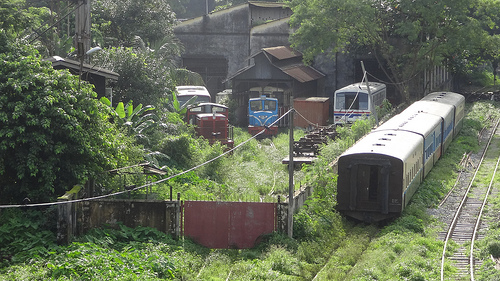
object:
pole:
[286, 95, 295, 245]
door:
[355, 164, 387, 212]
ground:
[433, 149, 448, 166]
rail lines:
[297, 207, 380, 280]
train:
[335, 81, 469, 227]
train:
[246, 95, 279, 138]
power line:
[12, 81, 373, 222]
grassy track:
[302, 217, 382, 281]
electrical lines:
[0, 72, 425, 209]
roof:
[229, 46, 324, 82]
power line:
[366, 68, 417, 83]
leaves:
[83, 102, 148, 144]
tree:
[3, 28, 153, 233]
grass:
[0, 90, 499, 279]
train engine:
[248, 95, 279, 139]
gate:
[180, 200, 277, 249]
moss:
[112, 209, 158, 224]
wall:
[117, 199, 190, 243]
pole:
[357, 61, 372, 116]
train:
[173, 85, 234, 155]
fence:
[0, 58, 389, 264]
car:
[331, 91, 466, 224]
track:
[302, 218, 382, 281]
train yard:
[0, 0, 499, 280]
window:
[335, 92, 369, 111]